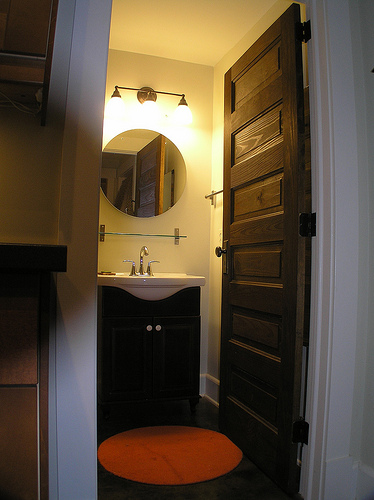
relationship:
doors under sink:
[97, 319, 197, 403] [115, 272, 184, 279]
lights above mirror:
[107, 85, 193, 129] [102, 130, 184, 216]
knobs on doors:
[146, 324, 162, 332] [97, 319, 197, 403]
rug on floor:
[99, 424, 246, 488] [96, 397, 294, 498]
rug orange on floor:
[99, 424, 246, 488] [96, 397, 294, 498]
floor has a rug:
[96, 397, 294, 498] [99, 424, 246, 488]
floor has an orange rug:
[96, 397, 294, 498] [99, 424, 246, 488]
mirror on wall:
[102, 130, 184, 216] [97, 49, 214, 277]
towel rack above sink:
[99, 226, 187, 244] [115, 272, 184, 279]